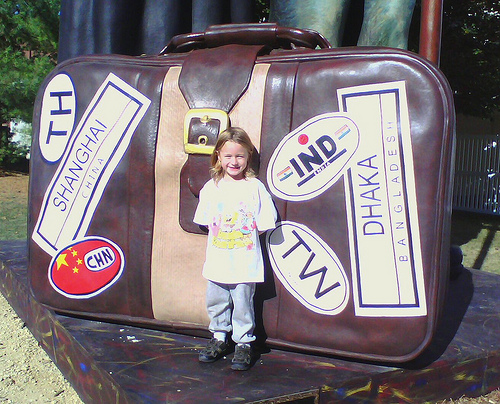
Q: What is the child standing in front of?
A: An enormous brown and green suitcase.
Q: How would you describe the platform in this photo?
A: It is decorated with red, yellow, and blue paint.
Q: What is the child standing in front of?
A: Sculpture.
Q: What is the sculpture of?
A: Suitcase.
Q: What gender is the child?
A: Female.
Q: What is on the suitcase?
A: Stickers.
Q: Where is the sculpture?
A: In the grass.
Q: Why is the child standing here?
A: For a picture.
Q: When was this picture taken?
A: During the afternoon.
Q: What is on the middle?
A: Buckle.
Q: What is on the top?
A: Handle.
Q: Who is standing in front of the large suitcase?
A: Little girl.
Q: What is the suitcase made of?
A: Leather.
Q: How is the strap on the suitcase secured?
A: Buckle.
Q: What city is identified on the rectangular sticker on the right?
A: Dhaka.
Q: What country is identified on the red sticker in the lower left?
A: China.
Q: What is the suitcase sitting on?
A: Platform.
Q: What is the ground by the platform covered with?
A: Rocks.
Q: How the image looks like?
A: Funny.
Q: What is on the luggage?
A: Various stickers.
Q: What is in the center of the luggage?
A: A buckle.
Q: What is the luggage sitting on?
A: Some sort of platform.